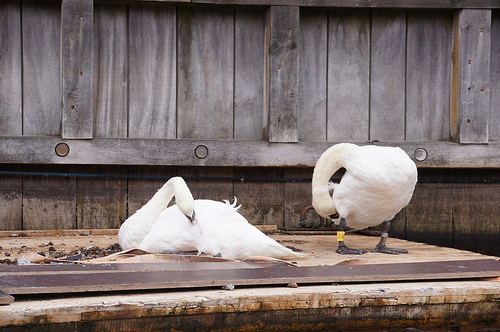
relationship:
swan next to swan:
[307, 139, 422, 254] [110, 176, 311, 264]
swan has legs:
[307, 139, 422, 254] [329, 212, 407, 256]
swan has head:
[307, 139, 422, 254] [297, 172, 343, 224]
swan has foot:
[307, 139, 422, 254] [327, 240, 368, 258]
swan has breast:
[307, 139, 422, 254] [346, 170, 412, 215]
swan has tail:
[307, 139, 422, 254] [326, 179, 337, 193]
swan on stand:
[307, 139, 422, 254] [1, 227, 498, 330]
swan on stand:
[110, 176, 311, 264] [1, 227, 498, 330]